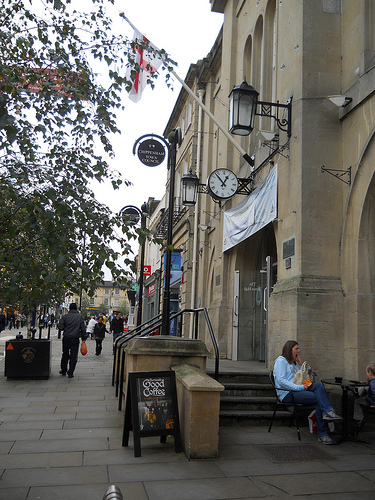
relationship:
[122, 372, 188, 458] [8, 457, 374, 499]
sign on top of sidewalk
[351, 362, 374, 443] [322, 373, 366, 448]
boy near table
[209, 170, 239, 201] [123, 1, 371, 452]
clock attached to building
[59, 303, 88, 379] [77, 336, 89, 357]
person has bag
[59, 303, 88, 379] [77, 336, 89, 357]
man has bag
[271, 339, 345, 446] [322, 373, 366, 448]
person near table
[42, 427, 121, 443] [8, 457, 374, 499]
blocks form sidewalk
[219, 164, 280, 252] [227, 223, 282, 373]
banner over entrance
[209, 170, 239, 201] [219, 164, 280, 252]
clock over banner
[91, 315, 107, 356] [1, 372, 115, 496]
person on top of sidewalk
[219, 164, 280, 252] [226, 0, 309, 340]
poster near wall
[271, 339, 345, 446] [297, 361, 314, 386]
lady has purse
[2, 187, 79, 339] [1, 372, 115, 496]
tree on top of sidewalk